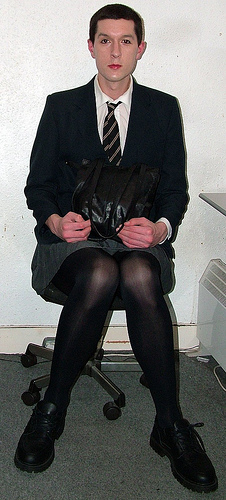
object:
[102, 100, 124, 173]
tie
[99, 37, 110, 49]
eye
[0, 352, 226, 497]
floor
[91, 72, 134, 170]
shirt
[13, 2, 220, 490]
man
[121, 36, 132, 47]
eye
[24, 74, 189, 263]
jacket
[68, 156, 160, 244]
purse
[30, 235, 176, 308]
dress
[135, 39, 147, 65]
ear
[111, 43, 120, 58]
nose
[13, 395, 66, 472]
shoe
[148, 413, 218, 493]
shoe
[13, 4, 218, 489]
girl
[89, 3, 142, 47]
hair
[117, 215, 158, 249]
hand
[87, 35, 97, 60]
ear